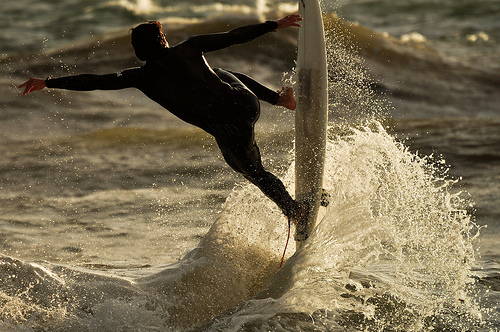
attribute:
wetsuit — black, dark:
[111, 45, 280, 188]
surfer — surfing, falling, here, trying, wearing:
[105, 11, 252, 140]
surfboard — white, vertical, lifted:
[292, 25, 328, 215]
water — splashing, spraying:
[83, 218, 223, 274]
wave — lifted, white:
[223, 210, 385, 325]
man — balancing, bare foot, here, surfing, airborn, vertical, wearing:
[107, 53, 253, 131]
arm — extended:
[50, 65, 115, 109]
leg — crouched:
[209, 134, 303, 232]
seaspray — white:
[331, 88, 444, 243]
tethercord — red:
[240, 218, 332, 273]